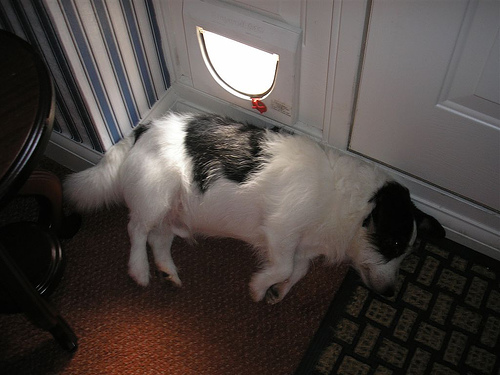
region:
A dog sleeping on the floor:
[62, 112, 447, 299]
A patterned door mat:
[297, 214, 495, 374]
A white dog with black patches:
[70, 110, 444, 303]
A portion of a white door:
[317, 7, 498, 261]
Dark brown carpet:
[4, 150, 349, 373]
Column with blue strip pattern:
[3, 0, 175, 175]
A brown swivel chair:
[0, 36, 83, 355]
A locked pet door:
[178, 3, 298, 126]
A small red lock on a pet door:
[248, 95, 266, 113]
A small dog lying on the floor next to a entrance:
[61, 112, 446, 299]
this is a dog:
[103, 123, 433, 335]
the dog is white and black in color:
[200, 152, 278, 230]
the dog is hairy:
[205, 142, 283, 212]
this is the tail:
[68, 165, 106, 205]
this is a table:
[6, 54, 60, 155]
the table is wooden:
[4, 66, 51, 159]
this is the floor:
[256, 307, 342, 362]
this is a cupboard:
[334, 55, 498, 120]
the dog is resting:
[87, 89, 452, 301]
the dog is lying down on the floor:
[82, 95, 437, 372]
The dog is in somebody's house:
[23, 7, 463, 368]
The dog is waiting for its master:
[10, 40, 485, 347]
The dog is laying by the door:
[8, 25, 493, 351]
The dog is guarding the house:
[5, 27, 493, 360]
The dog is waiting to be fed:
[15, 32, 480, 342]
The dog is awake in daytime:
[11, 28, 491, 354]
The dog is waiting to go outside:
[5, 20, 491, 350]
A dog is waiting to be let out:
[20, 20, 481, 370]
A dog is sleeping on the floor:
[15, 42, 495, 337]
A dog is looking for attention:
[9, 12, 473, 337]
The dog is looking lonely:
[7, 22, 493, 363]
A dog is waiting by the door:
[20, 35, 480, 368]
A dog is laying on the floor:
[12, 40, 472, 351]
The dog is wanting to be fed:
[5, 40, 488, 368]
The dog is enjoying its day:
[8, 40, 473, 355]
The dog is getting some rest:
[37, 47, 487, 332]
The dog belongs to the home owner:
[7, 19, 485, 348]